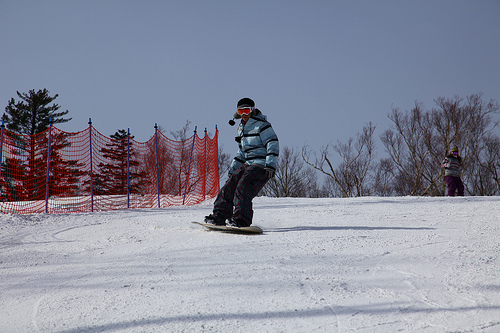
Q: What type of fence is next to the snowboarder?
A: Plastic fence.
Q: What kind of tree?
A: Pine.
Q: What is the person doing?
A: Snowboarding.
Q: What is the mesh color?
A: Red.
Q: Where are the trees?
A: Hill.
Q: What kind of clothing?
A: Winter.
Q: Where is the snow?
A: Hill.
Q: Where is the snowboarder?
A: Hill.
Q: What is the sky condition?
A: Clear.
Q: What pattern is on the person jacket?
A: Striped pattern.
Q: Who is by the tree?
A: The guy in the back.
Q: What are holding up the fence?
A: Blue poles.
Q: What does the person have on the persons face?
A: Orange goggles.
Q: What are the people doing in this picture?
A: Snow-boarding.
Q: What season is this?
A: Winter.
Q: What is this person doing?
A: Snowboarding.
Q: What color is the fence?
A: Orange.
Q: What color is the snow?
A: White.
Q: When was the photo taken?
A: During the day.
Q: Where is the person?
A: On a ski hill.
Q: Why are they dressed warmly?
A: It's cold out.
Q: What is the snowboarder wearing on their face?
A: Goggles.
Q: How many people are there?
A: One.